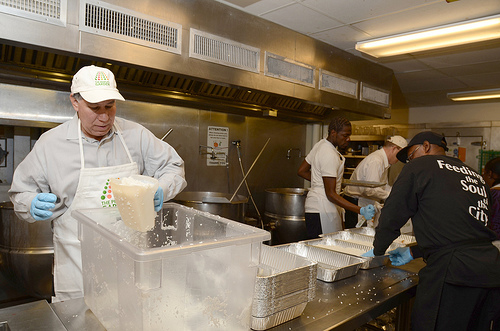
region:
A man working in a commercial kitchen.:
[8, 63, 188, 300]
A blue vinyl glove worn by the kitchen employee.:
[28, 191, 59, 222]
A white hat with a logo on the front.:
[68, 62, 126, 105]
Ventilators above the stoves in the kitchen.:
[141, 47, 397, 110]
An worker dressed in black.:
[364, 130, 498, 327]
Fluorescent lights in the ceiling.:
[348, 47, 498, 106]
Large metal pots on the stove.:
[175, 180, 317, 225]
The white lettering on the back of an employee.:
[433, 157, 498, 229]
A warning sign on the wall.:
[203, 124, 231, 166]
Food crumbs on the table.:
[319, 272, 405, 312]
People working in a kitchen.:
[21, 12, 495, 324]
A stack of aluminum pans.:
[253, 238, 318, 328]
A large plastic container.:
[73, 199, 260, 329]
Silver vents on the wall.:
[16, 0, 402, 106]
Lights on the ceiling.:
[335, 8, 495, 113]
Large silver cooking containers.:
[186, 170, 315, 227]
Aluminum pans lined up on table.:
[300, 223, 415, 283]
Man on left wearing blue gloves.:
[13, 60, 180, 222]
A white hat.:
[60, 57, 132, 126]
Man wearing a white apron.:
[21, 57, 188, 312]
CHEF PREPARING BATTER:
[19, 38, 216, 326]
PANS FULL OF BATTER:
[308, 214, 411, 292]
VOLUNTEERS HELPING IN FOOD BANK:
[26, 59, 490, 328]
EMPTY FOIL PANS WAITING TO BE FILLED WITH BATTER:
[240, 234, 324, 324]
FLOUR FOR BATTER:
[106, 166, 176, 233]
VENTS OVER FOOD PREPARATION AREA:
[262, 46, 403, 122]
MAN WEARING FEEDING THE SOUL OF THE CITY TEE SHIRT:
[373, 128, 491, 299]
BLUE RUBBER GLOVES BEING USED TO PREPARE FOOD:
[10, 174, 71, 231]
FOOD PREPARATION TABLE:
[255, 246, 415, 328]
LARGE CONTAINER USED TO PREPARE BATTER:
[74, 196, 276, 327]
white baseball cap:
[65, 52, 127, 109]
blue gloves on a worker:
[22, 189, 62, 222]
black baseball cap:
[391, 130, 457, 162]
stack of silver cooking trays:
[239, 233, 321, 329]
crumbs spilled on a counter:
[327, 291, 387, 312]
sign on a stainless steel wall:
[199, 121, 236, 171]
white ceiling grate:
[182, 22, 278, 79]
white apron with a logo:
[55, 118, 154, 310]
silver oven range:
[134, 66, 267, 119]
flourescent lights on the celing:
[344, 23, 496, 61]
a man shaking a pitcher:
[14, 68, 181, 300]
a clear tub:
[87, 218, 254, 330]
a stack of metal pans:
[258, 250, 317, 328]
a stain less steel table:
[330, 274, 397, 329]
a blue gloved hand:
[386, 246, 413, 271]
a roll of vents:
[261, 53, 396, 108]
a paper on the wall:
[204, 122, 230, 167]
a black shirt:
[373, 161, 496, 263]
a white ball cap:
[71, 68, 133, 105]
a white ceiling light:
[361, 15, 499, 65]